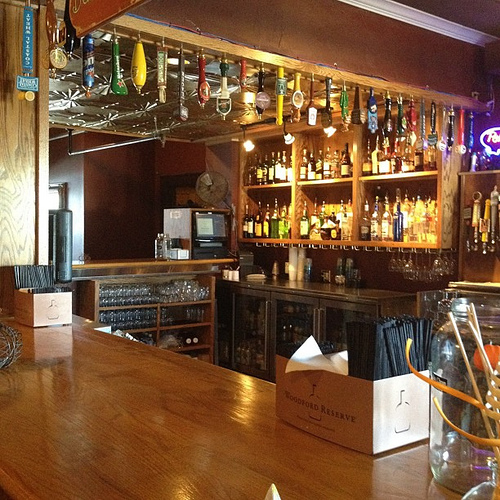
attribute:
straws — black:
[344, 312, 436, 379]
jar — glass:
[421, 287, 498, 494]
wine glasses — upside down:
[387, 248, 456, 285]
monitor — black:
[184, 212, 233, 252]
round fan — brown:
[197, 170, 227, 204]